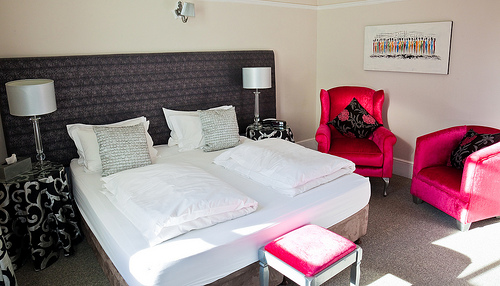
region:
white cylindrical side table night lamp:
[5, 75, 63, 164]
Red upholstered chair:
[408, 123, 497, 231]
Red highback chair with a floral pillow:
[315, 82, 399, 194]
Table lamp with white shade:
[241, 63, 271, 125]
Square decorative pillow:
[93, 126, 151, 176]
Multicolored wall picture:
[360, 21, 455, 75]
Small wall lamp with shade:
[173, 1, 198, 26]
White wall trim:
[283, 0, 358, 12]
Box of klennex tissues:
[1, 150, 32, 180]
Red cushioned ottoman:
[261, 220, 368, 285]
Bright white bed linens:
[118, 162, 253, 233]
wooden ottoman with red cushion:
[256, 209, 369, 284]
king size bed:
[51, 122, 400, 284]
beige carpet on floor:
[389, 214, 434, 284]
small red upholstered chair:
[401, 113, 498, 221]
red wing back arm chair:
[311, 86, 408, 185]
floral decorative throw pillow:
[331, 100, 379, 148]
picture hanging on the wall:
[356, 20, 458, 83]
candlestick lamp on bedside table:
[4, 69, 67, 181]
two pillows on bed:
[66, 116, 169, 173]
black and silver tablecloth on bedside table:
[3, 164, 88, 278]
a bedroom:
[7, 7, 493, 273]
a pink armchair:
[311, 87, 403, 172]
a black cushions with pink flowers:
[328, 101, 386, 149]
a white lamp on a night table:
[6, 78, 76, 175]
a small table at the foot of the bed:
[255, 225, 375, 285]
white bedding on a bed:
[104, 145, 380, 248]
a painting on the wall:
[351, 21, 466, 77]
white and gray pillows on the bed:
[68, 106, 248, 163]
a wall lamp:
[168, 1, 202, 26]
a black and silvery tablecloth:
[12, 161, 83, 256]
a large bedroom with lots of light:
[4, 3, 499, 285]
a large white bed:
[71, 119, 369, 284]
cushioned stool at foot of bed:
[218, 184, 372, 284]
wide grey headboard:
[0, 45, 274, 162]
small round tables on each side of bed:
[11, 114, 308, 266]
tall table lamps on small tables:
[1, 64, 287, 191]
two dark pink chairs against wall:
[313, 78, 498, 236]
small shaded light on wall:
[168, 0, 208, 32]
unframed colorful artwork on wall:
[351, 14, 468, 83]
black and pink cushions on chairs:
[324, 94, 498, 170]